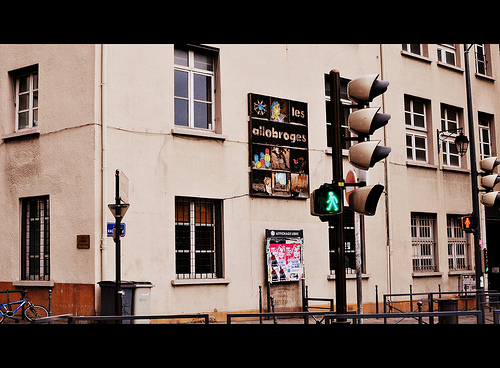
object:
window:
[174, 196, 222, 281]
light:
[349, 184, 385, 216]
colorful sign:
[248, 92, 311, 198]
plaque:
[77, 235, 90, 249]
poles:
[259, 284, 468, 324]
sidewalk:
[150, 308, 500, 325]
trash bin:
[97, 280, 131, 324]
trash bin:
[129, 281, 154, 324]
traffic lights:
[476, 156, 499, 206]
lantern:
[455, 135, 469, 158]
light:
[310, 183, 344, 216]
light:
[349, 139, 392, 170]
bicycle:
[0, 285, 52, 324]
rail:
[0, 290, 27, 293]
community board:
[266, 229, 304, 284]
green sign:
[326, 191, 339, 211]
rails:
[383, 290, 499, 325]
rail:
[70, 310, 500, 325]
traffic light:
[310, 69, 389, 217]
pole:
[330, 69, 347, 323]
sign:
[106, 220, 129, 239]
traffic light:
[347, 105, 390, 135]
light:
[344, 75, 386, 104]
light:
[465, 218, 471, 229]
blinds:
[174, 197, 216, 223]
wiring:
[40, 123, 326, 153]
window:
[171, 43, 217, 135]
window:
[13, 66, 38, 133]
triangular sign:
[107, 202, 128, 220]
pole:
[115, 170, 123, 324]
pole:
[462, 43, 486, 325]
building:
[0, 42, 500, 324]